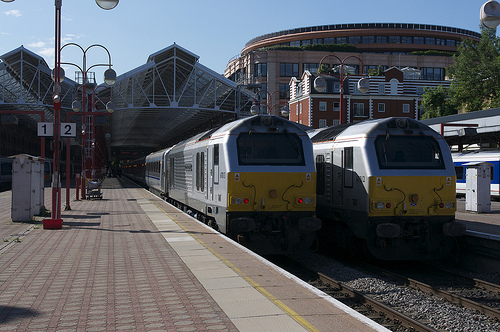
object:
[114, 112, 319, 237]
train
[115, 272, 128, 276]
brick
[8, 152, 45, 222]
box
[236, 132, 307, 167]
windshield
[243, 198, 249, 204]
ligh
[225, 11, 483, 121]
building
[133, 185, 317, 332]
line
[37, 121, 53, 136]
sign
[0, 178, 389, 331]
walkway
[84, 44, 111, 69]
pole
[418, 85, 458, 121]
tree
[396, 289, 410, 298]
rock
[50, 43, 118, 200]
lamp